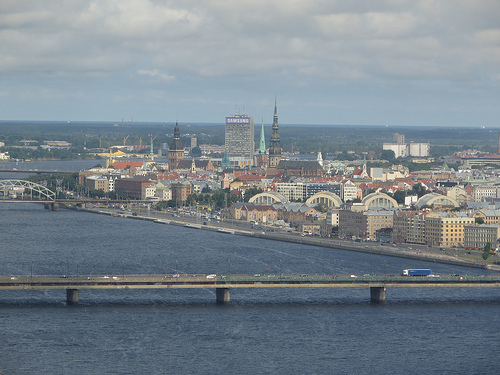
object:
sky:
[1, 2, 500, 128]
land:
[0, 122, 499, 271]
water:
[1, 199, 500, 373]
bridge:
[0, 272, 499, 307]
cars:
[60, 275, 70, 279]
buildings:
[462, 223, 500, 252]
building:
[222, 115, 255, 160]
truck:
[401, 268, 433, 277]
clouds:
[1, 1, 500, 96]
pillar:
[65, 287, 78, 305]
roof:
[112, 160, 143, 170]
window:
[446, 221, 449, 223]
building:
[421, 210, 476, 249]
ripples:
[371, 323, 499, 373]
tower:
[267, 92, 282, 173]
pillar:
[215, 286, 234, 305]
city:
[0, 94, 500, 264]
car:
[205, 274, 216, 279]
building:
[149, 138, 156, 165]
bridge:
[0, 177, 166, 212]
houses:
[170, 178, 194, 208]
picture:
[2, 2, 499, 375]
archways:
[413, 190, 458, 211]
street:
[73, 191, 499, 271]